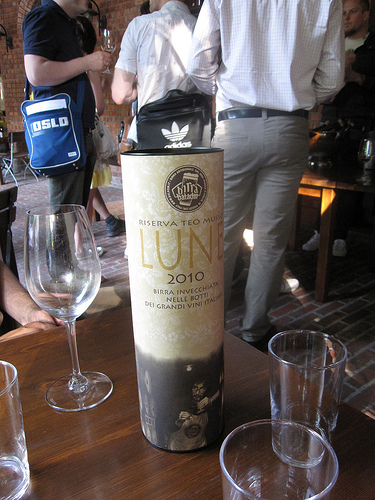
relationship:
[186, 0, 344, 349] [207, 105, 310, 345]
person wearing grey pants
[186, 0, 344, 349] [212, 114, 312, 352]
person wearing gray pants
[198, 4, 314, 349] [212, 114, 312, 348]
person wearing gray pants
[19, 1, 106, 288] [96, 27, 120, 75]
man holding wine glass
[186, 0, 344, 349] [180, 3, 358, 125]
person wearing shirt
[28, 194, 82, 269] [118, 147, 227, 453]
glass for wine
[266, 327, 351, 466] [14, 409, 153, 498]
glass on table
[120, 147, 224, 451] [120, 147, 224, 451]
wine bottle in wine bottle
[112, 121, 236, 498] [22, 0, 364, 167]
wine tasting event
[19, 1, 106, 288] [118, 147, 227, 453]
man waiting for wine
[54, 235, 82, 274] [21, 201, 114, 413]
water spots on glass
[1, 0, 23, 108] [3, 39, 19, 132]
walls made of bricks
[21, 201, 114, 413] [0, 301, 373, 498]
glass on table